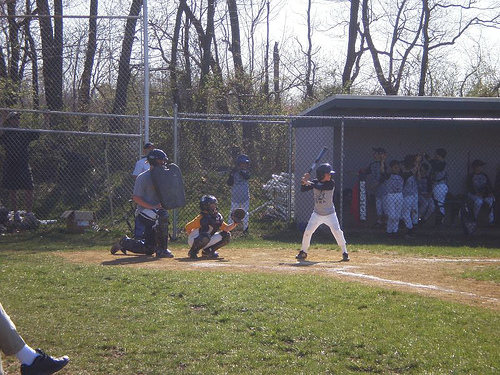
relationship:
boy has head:
[293, 159, 350, 263] [313, 166, 336, 185]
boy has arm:
[293, 159, 350, 263] [307, 177, 334, 192]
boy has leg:
[293, 159, 349, 262] [325, 213, 348, 254]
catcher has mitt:
[180, 193, 247, 258] [227, 207, 252, 227]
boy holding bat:
[293, 159, 350, 263] [306, 143, 326, 177]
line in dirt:
[332, 266, 479, 298] [62, 245, 498, 312]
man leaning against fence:
[0, 103, 49, 229] [5, 123, 139, 238]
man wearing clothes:
[0, 103, 49, 229] [0, 125, 44, 194]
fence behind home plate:
[2, 102, 499, 239] [308, 257, 343, 269]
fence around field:
[2, 102, 499, 239] [3, 233, 498, 371]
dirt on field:
[38, 240, 498, 313] [3, 233, 498, 371]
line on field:
[332, 266, 479, 298] [3, 233, 498, 371]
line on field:
[336, 254, 497, 269] [3, 233, 498, 371]